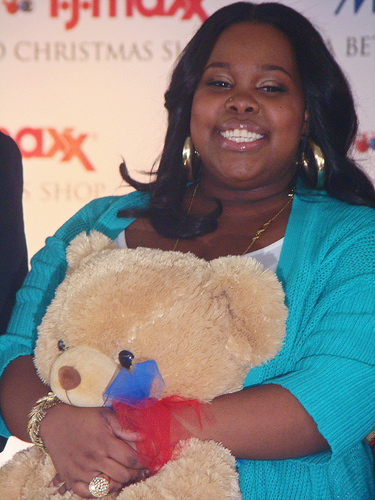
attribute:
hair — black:
[282, 11, 348, 153]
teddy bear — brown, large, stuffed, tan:
[53, 243, 231, 498]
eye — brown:
[123, 344, 134, 365]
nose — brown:
[53, 360, 91, 407]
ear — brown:
[218, 244, 302, 365]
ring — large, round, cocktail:
[97, 476, 114, 493]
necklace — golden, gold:
[247, 205, 269, 246]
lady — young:
[28, 25, 354, 460]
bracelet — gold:
[23, 393, 72, 447]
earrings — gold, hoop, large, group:
[295, 141, 322, 199]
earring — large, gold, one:
[172, 137, 204, 192]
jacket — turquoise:
[32, 198, 344, 499]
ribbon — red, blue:
[126, 374, 201, 459]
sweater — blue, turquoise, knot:
[282, 207, 374, 455]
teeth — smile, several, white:
[213, 127, 271, 150]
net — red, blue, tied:
[125, 378, 201, 485]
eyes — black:
[59, 331, 126, 372]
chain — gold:
[226, 214, 315, 249]